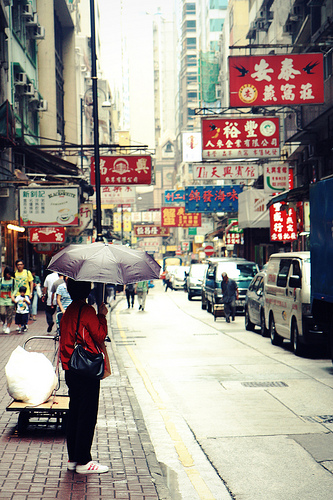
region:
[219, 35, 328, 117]
a sign on building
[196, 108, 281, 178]
a sign on building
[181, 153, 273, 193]
a sign on building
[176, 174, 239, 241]
a sign on building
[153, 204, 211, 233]
a sign on building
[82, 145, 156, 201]
a sign on building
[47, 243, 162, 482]
woman looking down street holding umbrella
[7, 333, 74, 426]
wheeled cart with large white bag on it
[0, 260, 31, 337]
family of 3 walking on sidewalk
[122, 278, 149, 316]
two headless people walking down street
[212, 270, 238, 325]
man with wheeled cart in street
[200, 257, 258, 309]
blue van parked on side of the street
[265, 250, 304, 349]
white van parked on side of street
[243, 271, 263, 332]
compact car parked between two vans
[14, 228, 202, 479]
person standing in rain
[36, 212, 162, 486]
person holding an umbrella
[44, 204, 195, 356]
an opened dark umbrella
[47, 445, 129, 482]
white shoes with red stripes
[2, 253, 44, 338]
family walking on a sidewalk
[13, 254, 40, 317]
man in a yellow shirt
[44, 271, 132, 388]
person in a red coat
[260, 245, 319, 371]
a white work van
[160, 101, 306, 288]
many different business signs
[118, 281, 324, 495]
part of a road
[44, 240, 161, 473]
a woman carrying a black purse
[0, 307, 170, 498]
a red brick umbrella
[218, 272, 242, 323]
a wearing jeans and a blue shirt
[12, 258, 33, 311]
a person wearing a yellow shirt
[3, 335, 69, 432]
a cart with a large white bag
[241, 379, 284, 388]
a water drainage hole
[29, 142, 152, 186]
a red sign on a metal pole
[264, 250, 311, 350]
a white colored van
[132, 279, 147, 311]
a person wearing a green shirt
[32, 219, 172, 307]
this is an umbrella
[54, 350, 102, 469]
woman wearing black pants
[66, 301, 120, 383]
woman carrying a purse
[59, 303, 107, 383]
the purse is black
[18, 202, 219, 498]
woman standing on sidewalk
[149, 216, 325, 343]
cars on the street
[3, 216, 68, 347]
people walking on the sidewalk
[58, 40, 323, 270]
multiple signs on the buildings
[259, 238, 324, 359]
a white van on the street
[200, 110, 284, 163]
Signs are written in Chinese.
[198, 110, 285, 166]
The sign is red and white.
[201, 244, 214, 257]
A street sign is visible.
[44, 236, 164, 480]
The woman has an umbrella.